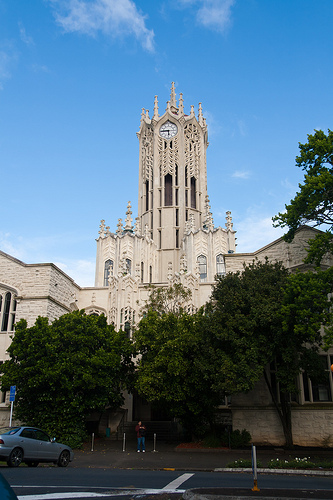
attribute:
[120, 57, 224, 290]
clock tower — ornate , stone 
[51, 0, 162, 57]
clouds — white 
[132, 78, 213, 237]
tower — tan, clock tower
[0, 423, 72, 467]
car — parked 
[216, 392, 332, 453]
wall — stone 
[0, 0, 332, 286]
clouds — white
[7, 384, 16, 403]
sign — blue 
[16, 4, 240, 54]
clouds — white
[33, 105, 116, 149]
sky — blue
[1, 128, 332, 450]
trees — tall , green 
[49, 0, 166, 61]
cloud — white 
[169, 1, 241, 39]
cloud — white 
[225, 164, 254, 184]
cloud — white 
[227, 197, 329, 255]
cloud — white 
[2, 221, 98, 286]
cloud — white 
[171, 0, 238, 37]
cloud — white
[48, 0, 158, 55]
cloud — white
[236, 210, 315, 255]
cloud — white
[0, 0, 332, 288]
sky — blue , clear 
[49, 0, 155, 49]
cloud — white 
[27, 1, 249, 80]
clouds — white